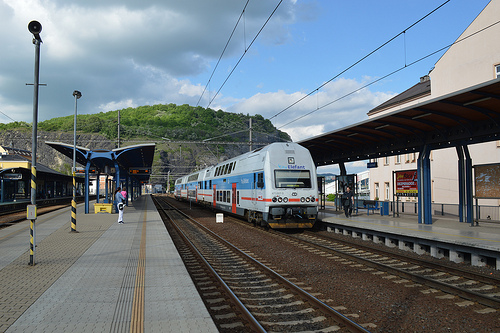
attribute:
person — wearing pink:
[119, 185, 129, 205]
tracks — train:
[302, 222, 436, 269]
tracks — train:
[161, 188, 263, 319]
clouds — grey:
[253, 59, 375, 150]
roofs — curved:
[43, 133, 159, 177]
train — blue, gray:
[166, 136, 326, 235]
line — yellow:
[128, 192, 151, 332]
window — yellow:
[367, 166, 409, 213]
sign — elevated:
[391, 170, 420, 210]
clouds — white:
[52, 24, 84, 51]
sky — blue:
[306, 11, 360, 78]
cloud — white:
[230, 93, 329, 122]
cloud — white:
[309, 73, 396, 111]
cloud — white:
[3, 2, 300, 103]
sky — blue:
[6, 0, 484, 141]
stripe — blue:
[170, 169, 268, 193]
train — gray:
[169, 139, 321, 231]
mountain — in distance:
[4, 100, 299, 192]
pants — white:
[115, 202, 129, 222]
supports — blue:
[80, 148, 127, 194]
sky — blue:
[253, 7, 467, 136]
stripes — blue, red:
[168, 174, 295, 194]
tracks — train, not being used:
[155, 191, 341, 330]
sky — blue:
[5, 3, 467, 132]